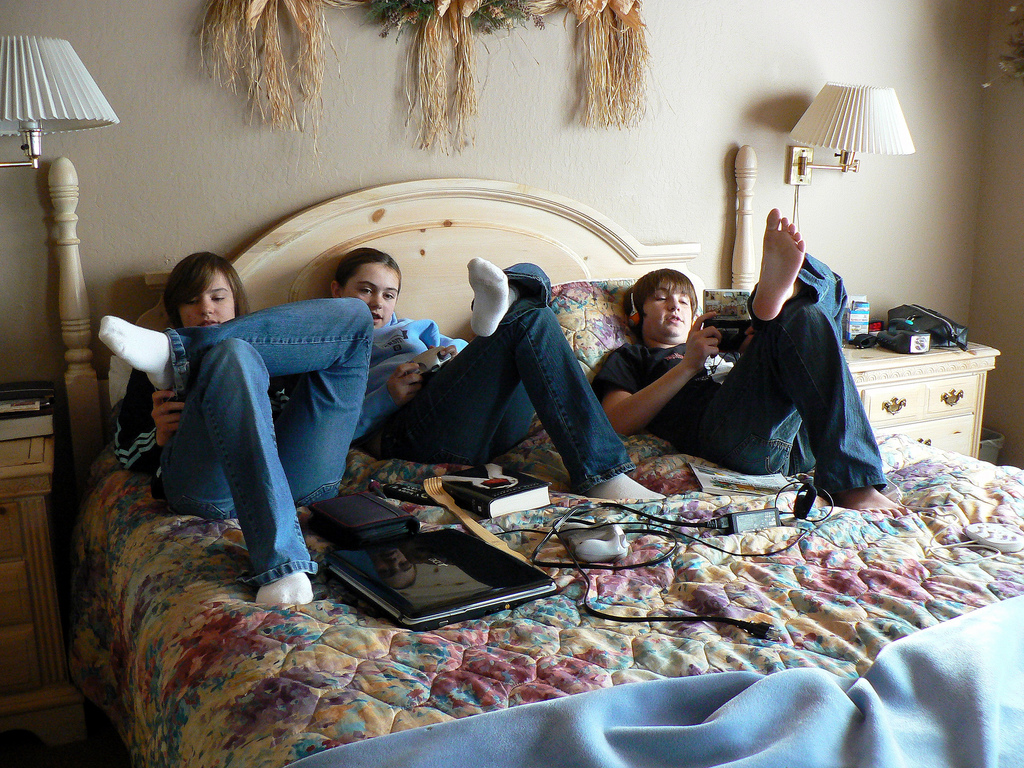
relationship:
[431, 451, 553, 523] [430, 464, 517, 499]
book with hand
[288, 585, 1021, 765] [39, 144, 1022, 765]
blanket on bed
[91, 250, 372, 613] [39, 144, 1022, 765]
kid laying on bed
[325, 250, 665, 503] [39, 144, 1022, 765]
kid laying on bed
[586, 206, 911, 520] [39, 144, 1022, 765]
kid laying on bed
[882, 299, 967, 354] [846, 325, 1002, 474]
bag on table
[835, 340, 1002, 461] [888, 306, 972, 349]
table has bag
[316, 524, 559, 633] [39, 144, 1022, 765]
laptop on bed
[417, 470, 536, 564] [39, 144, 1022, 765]
back scratcher on bed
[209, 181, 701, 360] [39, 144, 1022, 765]
headboard to bed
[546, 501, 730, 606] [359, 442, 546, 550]
control with buttons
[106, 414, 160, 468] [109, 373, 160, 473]
stripes on sleeve